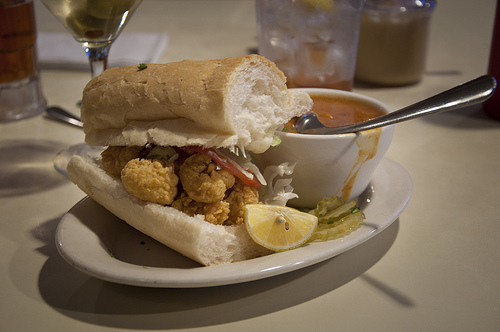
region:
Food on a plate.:
[35, 30, 368, 299]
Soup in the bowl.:
[223, 55, 430, 254]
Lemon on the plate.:
[94, 84, 391, 307]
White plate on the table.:
[11, 137, 336, 331]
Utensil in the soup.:
[286, 66, 481, 169]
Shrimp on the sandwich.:
[51, 115, 274, 260]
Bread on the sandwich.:
[103, 19, 337, 171]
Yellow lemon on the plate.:
[222, 167, 351, 274]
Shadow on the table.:
[338, 243, 445, 327]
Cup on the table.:
[243, 5, 420, 133]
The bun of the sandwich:
[80, 57, 284, 151]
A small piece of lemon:
[241, 203, 315, 245]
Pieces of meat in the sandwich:
[116, 145, 258, 220]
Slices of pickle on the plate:
[316, 195, 372, 236]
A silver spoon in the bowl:
[297, 75, 492, 135]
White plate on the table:
[56, 151, 412, 295]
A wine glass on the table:
[56, 0, 139, 177]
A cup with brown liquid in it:
[0, 0, 52, 116]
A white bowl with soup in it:
[274, 85, 393, 205]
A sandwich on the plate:
[72, 56, 299, 266]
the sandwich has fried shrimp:
[101, 142, 253, 227]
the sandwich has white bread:
[56, 64, 301, 265]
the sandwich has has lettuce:
[224, 145, 299, 205]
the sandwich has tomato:
[207, 145, 258, 188]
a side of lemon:
[245, 202, 310, 243]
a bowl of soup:
[271, 87, 392, 202]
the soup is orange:
[287, 96, 379, 126]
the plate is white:
[53, 157, 409, 284]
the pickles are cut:
[307, 191, 358, 239]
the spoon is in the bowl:
[297, 78, 494, 134]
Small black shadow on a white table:
[32, 284, 111, 324]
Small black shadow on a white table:
[96, 281, 158, 328]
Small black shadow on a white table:
[185, 287, 260, 317]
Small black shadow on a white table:
[272, 273, 354, 300]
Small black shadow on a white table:
[342, 253, 417, 320]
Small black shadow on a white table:
[365, 240, 417, 255]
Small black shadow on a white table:
[15, 131, 37, 164]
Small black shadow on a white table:
[27, 157, 53, 188]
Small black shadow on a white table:
[6, 152, 27, 217]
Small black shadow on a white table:
[29, 126, 61, 168]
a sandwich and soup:
[50, 47, 415, 275]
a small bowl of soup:
[276, 78, 398, 244]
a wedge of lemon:
[242, 179, 341, 267]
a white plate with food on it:
[35, 127, 454, 324]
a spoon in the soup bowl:
[280, 65, 497, 147]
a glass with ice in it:
[260, 12, 371, 100]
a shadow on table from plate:
[11, 170, 431, 328]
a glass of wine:
[47, 0, 147, 133]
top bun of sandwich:
[75, 49, 317, 159]